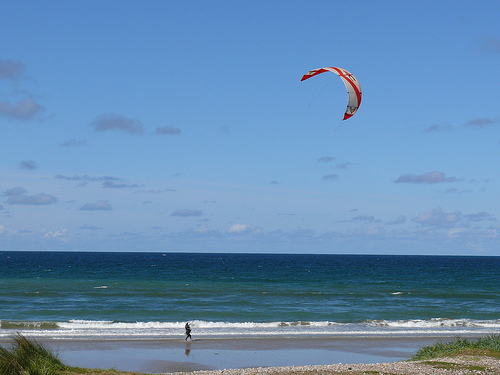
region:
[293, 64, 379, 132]
the kite is in the air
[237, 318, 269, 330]
the water has waves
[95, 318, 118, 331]
the waves are white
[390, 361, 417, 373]
the gravel is gray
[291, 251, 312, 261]
the water is dark blue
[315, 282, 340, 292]
the water is teal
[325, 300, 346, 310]
the water is light blue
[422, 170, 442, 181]
the clouds are gray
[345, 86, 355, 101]
the kite is white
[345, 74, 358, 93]
the kite is red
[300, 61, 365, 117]
red and white kite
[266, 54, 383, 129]
red stripe on kite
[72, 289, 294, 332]
white waves on water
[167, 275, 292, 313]
water is dark blue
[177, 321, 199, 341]
person is on beach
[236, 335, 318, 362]
sand is dark brown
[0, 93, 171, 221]
blue and white sky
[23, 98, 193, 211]
few small clouds in sky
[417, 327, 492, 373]
green grass near beach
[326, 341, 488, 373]
stone path near beach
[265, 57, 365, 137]
red and white kite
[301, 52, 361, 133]
red stripe on kite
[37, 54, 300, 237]
blue and white sky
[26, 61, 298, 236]
small white and grey clouds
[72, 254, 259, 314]
water is dark blue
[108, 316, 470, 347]
white wave reaching shore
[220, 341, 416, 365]
sand is dark grey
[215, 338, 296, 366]
sand is wet from ocean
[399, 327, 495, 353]
green grass near sand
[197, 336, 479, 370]
grey path behind beach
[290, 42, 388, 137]
this is a kite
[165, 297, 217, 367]
this is a person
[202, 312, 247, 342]
this is a wave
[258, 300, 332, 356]
this is a wave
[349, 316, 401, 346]
this is a wave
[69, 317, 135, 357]
this is a wave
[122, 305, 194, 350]
this is a wave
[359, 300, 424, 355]
this is a wave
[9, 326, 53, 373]
this is a patch of grass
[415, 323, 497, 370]
this is a patch of grass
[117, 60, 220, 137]
this is the sky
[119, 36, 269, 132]
the sky is blue in color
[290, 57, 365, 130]
this is the kite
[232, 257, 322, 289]
this is a water body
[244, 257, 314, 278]
the water is calm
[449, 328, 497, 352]
this is a grass area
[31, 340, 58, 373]
the grass is green in color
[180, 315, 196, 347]
this is a man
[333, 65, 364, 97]
the kite is white and red in color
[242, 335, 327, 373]
this is the beach